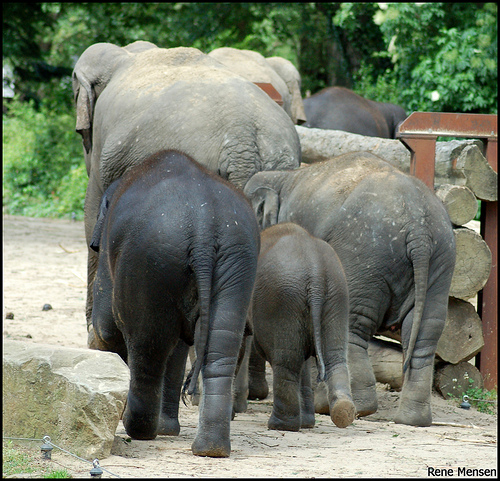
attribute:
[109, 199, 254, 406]
elephant — black, lit, baby, back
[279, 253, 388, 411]
elephant — smallest, baby, center, small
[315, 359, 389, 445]
leg — airborn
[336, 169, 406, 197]
paint — white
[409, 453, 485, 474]
photographer — rene mensen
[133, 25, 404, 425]
elephants — six, social, walking, dirty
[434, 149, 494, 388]
logs — stacked, together, wooden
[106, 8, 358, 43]
leaves — green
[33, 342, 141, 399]
rock — flat, large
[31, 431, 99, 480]
hooks — metal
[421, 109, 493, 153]
rack — rusted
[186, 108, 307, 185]
skin — wrinkled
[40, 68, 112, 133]
ear — folded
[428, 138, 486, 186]
log — cut, stacked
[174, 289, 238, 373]
tails — short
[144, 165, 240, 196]
spots — dark, white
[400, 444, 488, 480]
text — black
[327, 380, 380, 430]
foot — gray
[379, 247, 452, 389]
tail — dusty, long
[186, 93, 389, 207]
wrinkles — big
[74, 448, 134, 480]
anchor — metal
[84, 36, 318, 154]
elephant — leading